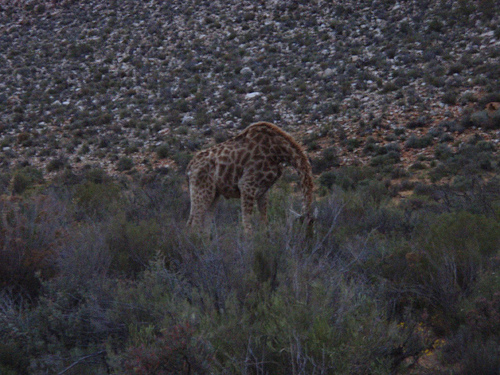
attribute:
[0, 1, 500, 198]
landscape — gravelled, gravelly, hill, stony, rocky, dirt, flowery, steep, brown, light grey, hillside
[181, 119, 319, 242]
giraffe — eating, standing, grazing, leaning over, brown, spotted, orange, bent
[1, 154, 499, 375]
grass — patched, gray, bushy, green, twiggy, gravelly, flowery, weedy, dirty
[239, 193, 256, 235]
leg — speckled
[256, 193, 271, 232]
leg — speckled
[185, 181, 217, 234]
leg — speckled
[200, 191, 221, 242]
leg — speckled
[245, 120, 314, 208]
mane — brown, curved, orange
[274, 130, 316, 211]
neck — bent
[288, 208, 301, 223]
ear — pointy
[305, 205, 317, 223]
ear — pointy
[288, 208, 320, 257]
head — down